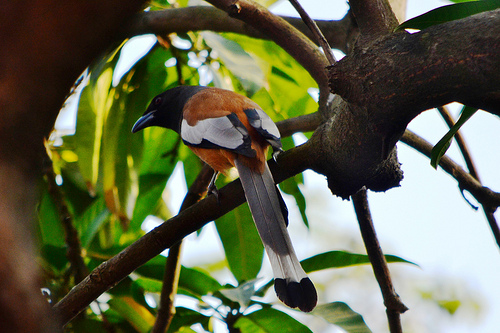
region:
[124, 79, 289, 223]
bird standing on branch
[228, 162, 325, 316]
long tail feathers on bird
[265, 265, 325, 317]
black edge of tail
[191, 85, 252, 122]
orange back on bird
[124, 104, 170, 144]
bird beak pointing left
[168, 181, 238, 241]
foot on tree branch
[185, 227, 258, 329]
green leaves in distance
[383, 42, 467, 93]
bark on tree branch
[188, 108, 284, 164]
two wings on bird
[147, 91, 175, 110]
eye on bird head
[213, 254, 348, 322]
the tail is black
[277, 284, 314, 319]
the tail is black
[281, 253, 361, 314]
the tail is black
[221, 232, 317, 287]
the tail is black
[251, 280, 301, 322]
the tail is black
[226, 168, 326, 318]
bird's tail is grey black and white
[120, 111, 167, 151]
bird's beak is present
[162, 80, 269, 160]
bird has brown grey black and white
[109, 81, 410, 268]
bird is on a branch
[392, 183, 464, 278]
the sky is cloudy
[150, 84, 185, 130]
bird's eye is open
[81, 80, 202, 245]
green leaves in background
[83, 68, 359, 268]
only one bird is present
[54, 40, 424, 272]
no other animal is present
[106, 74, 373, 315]
bird is looking to the left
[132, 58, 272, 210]
a bird on tree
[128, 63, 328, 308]
a bird on tree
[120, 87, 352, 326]
a cute beautiful bird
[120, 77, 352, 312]
a beautiful bird sitting on plant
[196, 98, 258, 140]
the beautiful color skin of bird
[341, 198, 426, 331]
a small piece of stem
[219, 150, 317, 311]
tail of the bird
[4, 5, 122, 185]
a part of the tree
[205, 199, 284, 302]
green leaf of the tree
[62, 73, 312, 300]
beautiful group of green leafs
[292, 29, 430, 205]
a big part of a plant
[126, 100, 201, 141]
nose of the bird